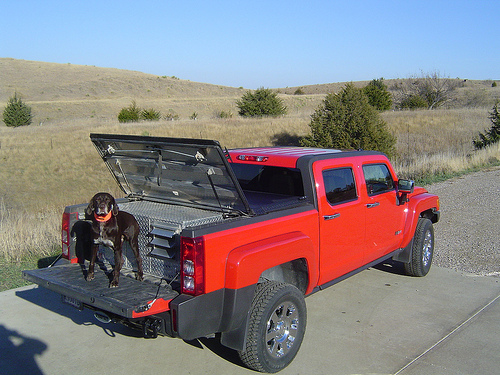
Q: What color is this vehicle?
A: Red.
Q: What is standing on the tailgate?
A: A dog.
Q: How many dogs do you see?
A: 1.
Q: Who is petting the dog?
A: No one.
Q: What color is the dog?
A: Brown.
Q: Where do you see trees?
A: In the field.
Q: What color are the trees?
A: Green.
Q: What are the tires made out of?
A: Rubber.